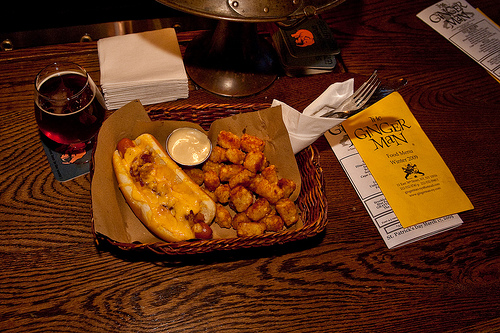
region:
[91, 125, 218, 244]
chilli cheese dog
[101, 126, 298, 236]
tator tots next to a chilli cheese dog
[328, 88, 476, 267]
yellow and white food menus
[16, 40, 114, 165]
drinking glass with liquid inside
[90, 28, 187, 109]
a stack of napkins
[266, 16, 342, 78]
red elephant on a coaster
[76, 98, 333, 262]
food in a rectangular basket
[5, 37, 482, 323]
a wooden table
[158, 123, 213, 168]
sauce in a black container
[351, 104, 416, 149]
menu for The Ginger Man restaurant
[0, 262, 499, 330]
a brown wooden table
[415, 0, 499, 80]
The Ginger Man food menu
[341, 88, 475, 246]
a yellow take home food menu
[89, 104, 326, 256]
a basket filled with food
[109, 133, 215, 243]
a cheese hotdog in a basket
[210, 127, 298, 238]
a basket of tater tots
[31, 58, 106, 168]
a wine goblet on the table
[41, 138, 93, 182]
a green and red glass coaster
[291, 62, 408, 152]
a knife and fork wrapped in a white napkin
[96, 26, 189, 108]
a stack of white napkins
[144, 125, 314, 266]
sandwich on a basket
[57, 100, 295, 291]
sandwich on a basket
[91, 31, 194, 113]
folded white table napkins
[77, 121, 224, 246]
sandwich on a basket